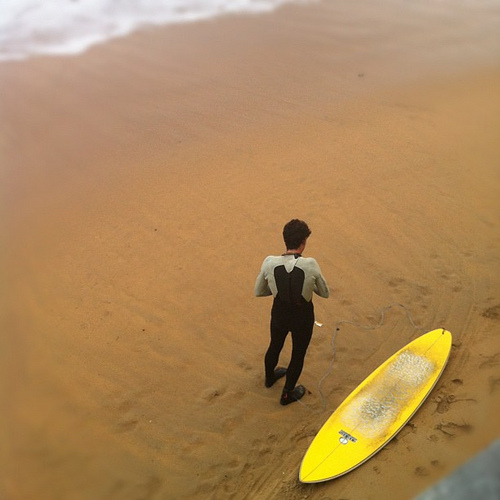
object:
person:
[254, 218, 331, 408]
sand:
[0, 0, 499, 498]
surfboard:
[296, 327, 453, 487]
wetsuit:
[253, 254, 329, 404]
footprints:
[125, 478, 161, 497]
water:
[0, 0, 282, 61]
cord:
[315, 296, 435, 421]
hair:
[281, 218, 313, 250]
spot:
[284, 392, 289, 400]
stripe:
[294, 322, 454, 487]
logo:
[337, 427, 357, 448]